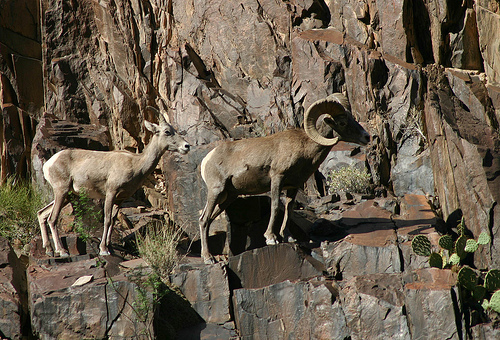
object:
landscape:
[0, 0, 500, 340]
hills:
[0, 166, 497, 340]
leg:
[198, 191, 221, 266]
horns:
[302, 98, 346, 146]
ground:
[0, 189, 500, 340]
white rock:
[70, 274, 95, 287]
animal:
[197, 92, 370, 265]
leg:
[263, 171, 283, 246]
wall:
[0, 0, 500, 340]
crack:
[0, 0, 500, 340]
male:
[198, 93, 371, 266]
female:
[36, 105, 191, 257]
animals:
[37, 105, 191, 256]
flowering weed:
[325, 164, 373, 195]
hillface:
[0, 0, 499, 340]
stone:
[325, 181, 461, 298]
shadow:
[218, 190, 463, 256]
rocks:
[0, 0, 499, 338]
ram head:
[299, 95, 358, 146]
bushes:
[0, 170, 46, 239]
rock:
[0, 0, 500, 340]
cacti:
[410, 207, 500, 327]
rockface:
[0, 1, 499, 340]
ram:
[196, 94, 373, 266]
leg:
[98, 197, 114, 255]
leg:
[36, 190, 72, 256]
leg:
[46, 177, 72, 257]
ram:
[28, 105, 191, 252]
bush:
[324, 166, 377, 194]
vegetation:
[130, 215, 196, 327]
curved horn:
[302, 97, 346, 146]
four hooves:
[41, 243, 112, 256]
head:
[302, 92, 372, 147]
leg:
[279, 188, 296, 245]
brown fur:
[213, 127, 324, 169]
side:
[2, 200, 497, 339]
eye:
[162, 129, 171, 136]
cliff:
[0, 0, 499, 340]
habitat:
[0, 0, 500, 340]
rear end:
[196, 151, 219, 182]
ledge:
[3, 203, 494, 340]